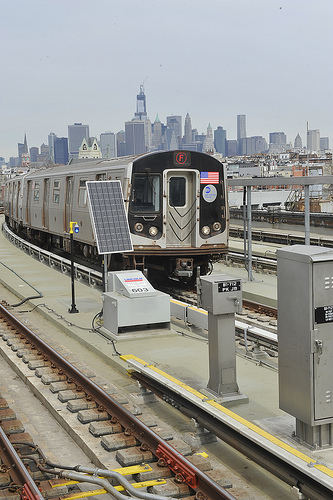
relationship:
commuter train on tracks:
[3, 142, 230, 297] [6, 217, 320, 482]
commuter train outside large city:
[3, 142, 230, 297] [6, 87, 326, 169]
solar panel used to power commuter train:
[87, 175, 142, 324] [3, 149, 230, 288]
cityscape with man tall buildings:
[13, 89, 330, 165] [2, 80, 331, 161]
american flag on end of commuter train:
[197, 170, 220, 182] [3, 149, 230, 288]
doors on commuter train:
[28, 176, 78, 234] [3, 149, 230, 288]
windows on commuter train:
[33, 176, 89, 201] [3, 149, 230, 288]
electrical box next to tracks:
[275, 239, 328, 447] [7, 306, 259, 496]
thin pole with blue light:
[66, 218, 82, 322] [72, 222, 85, 237]